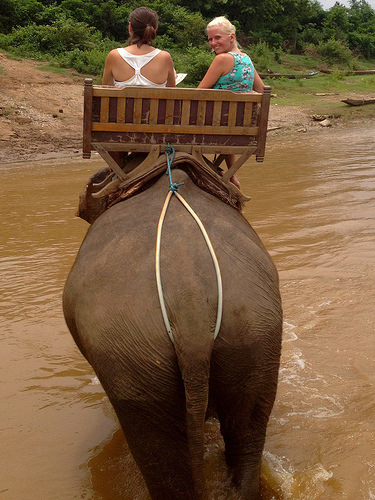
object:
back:
[218, 53, 260, 90]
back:
[103, 47, 172, 82]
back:
[60, 205, 281, 493]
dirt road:
[19, 78, 68, 128]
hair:
[205, 13, 244, 55]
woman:
[194, 13, 267, 191]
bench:
[72, 77, 322, 181]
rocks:
[310, 110, 340, 130]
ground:
[0, 64, 371, 145]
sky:
[314, 0, 374, 15]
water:
[296, 147, 364, 218]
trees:
[2, 0, 372, 76]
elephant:
[51, 162, 299, 496]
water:
[7, 112, 373, 465]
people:
[101, 6, 264, 92]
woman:
[96, 5, 177, 85]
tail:
[174, 342, 212, 499]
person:
[195, 15, 263, 92]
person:
[100, 7, 176, 88]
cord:
[154, 142, 223, 345]